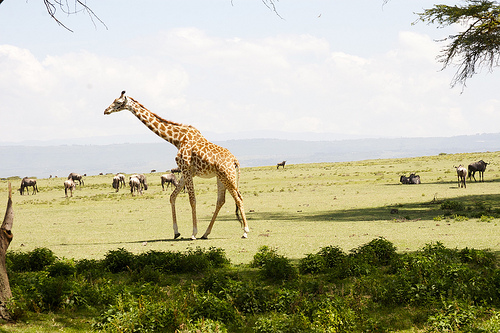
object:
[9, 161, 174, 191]
animal herd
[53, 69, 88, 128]
sky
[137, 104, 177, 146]
neck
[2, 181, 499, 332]
field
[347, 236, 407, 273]
plants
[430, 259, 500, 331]
shrubs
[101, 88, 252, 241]
giraffe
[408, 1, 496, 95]
tree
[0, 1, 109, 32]
tree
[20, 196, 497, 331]
ground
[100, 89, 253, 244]
animal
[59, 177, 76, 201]
animal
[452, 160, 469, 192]
animal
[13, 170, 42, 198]
animal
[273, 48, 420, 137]
sky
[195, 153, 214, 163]
spots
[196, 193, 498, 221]
shadow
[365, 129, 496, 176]
foothill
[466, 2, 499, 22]
leaves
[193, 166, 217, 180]
stomach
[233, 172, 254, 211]
tail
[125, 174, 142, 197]
animal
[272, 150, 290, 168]
animal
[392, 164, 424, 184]
animal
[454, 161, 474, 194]
animal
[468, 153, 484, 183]
animal